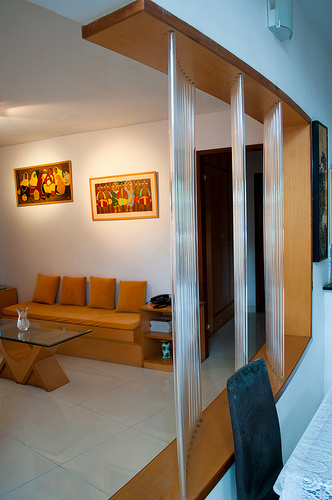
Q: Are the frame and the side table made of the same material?
A: Yes, both the frame and the side table are made of wood.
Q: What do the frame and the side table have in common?
A: The material, both the frame and the side table are wooden.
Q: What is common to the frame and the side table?
A: The material, both the frame and the side table are wooden.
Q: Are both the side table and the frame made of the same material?
A: Yes, both the side table and the frame are made of wood.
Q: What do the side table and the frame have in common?
A: The material, both the side table and the frame are wooden.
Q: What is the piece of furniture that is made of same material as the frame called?
A: The piece of furniture is a side table.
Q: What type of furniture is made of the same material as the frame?
A: The side table is made of the same material as the frame.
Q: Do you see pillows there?
A: Yes, there is a pillow.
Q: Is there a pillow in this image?
A: Yes, there is a pillow.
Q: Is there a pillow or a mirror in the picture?
A: Yes, there is a pillow.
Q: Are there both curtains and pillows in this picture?
A: No, there is a pillow but no curtains.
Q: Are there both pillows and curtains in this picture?
A: No, there is a pillow but no curtains.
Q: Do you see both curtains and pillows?
A: No, there is a pillow but no curtains.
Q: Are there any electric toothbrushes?
A: No, there are no electric toothbrushes.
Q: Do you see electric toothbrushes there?
A: No, there are no electric toothbrushes.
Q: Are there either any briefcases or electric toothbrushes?
A: No, there are no electric toothbrushes or briefcases.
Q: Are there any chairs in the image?
A: Yes, there is a chair.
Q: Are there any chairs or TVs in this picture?
A: Yes, there is a chair.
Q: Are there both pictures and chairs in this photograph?
A: Yes, there are both a chair and a picture.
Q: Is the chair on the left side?
A: No, the chair is on the right of the image.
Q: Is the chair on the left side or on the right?
A: The chair is on the right of the image.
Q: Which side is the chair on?
A: The chair is on the right of the image.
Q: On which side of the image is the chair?
A: The chair is on the right of the image.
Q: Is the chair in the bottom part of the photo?
A: Yes, the chair is in the bottom of the image.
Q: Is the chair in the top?
A: No, the chair is in the bottom of the image.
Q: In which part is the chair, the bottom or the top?
A: The chair is in the bottom of the image.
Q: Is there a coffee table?
A: Yes, there is a coffee table.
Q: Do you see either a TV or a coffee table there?
A: Yes, there is a coffee table.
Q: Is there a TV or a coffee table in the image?
A: Yes, there is a coffee table.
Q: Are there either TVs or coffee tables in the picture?
A: Yes, there is a coffee table.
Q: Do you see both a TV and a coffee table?
A: No, there is a coffee table but no televisions.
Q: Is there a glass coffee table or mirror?
A: Yes, there is a glass coffee table.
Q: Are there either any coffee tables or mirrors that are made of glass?
A: Yes, the coffee table is made of glass.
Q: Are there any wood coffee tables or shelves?
A: Yes, there is a wood coffee table.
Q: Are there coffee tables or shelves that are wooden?
A: Yes, the coffee table is wooden.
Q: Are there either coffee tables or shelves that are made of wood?
A: Yes, the coffee table is made of wood.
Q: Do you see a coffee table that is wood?
A: Yes, there is a wood coffee table.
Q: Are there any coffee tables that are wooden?
A: Yes, there is a coffee table that is wooden.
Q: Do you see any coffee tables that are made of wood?
A: Yes, there is a coffee table that is made of wood.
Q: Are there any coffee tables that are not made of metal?
A: Yes, there is a coffee table that is made of wood.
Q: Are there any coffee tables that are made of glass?
A: Yes, there is a coffee table that is made of glass.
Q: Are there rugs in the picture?
A: No, there are no rugs.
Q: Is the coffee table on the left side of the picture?
A: Yes, the coffee table is on the left of the image.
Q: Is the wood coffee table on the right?
A: No, the coffee table is on the left of the image.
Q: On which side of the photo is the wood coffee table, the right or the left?
A: The coffee table is on the left of the image.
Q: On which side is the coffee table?
A: The coffee table is on the left of the image.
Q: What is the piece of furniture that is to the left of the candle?
A: The piece of furniture is a coffee table.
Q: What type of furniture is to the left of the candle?
A: The piece of furniture is a coffee table.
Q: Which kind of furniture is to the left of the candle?
A: The piece of furniture is a coffee table.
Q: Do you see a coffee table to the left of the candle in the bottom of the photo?
A: Yes, there is a coffee table to the left of the candle.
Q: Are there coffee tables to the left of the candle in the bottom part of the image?
A: Yes, there is a coffee table to the left of the candle.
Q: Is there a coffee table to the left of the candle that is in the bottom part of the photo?
A: Yes, there is a coffee table to the left of the candle.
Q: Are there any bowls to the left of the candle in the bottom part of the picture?
A: No, there is a coffee table to the left of the candle.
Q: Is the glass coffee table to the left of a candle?
A: Yes, the coffee table is to the left of a candle.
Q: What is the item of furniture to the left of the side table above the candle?
A: The piece of furniture is a coffee table.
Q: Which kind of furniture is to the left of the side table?
A: The piece of furniture is a coffee table.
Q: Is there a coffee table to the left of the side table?
A: Yes, there is a coffee table to the left of the side table.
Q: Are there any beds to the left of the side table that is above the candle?
A: No, there is a coffee table to the left of the side table.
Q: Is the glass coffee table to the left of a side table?
A: Yes, the coffee table is to the left of a side table.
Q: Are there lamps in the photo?
A: No, there are no lamps.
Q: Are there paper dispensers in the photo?
A: No, there are no paper dispensers.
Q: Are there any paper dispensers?
A: No, there are no paper dispensers.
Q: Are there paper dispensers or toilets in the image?
A: No, there are no paper dispensers or toilets.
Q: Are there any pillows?
A: Yes, there is a pillow.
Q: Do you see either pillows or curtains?
A: Yes, there is a pillow.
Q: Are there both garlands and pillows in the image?
A: No, there is a pillow but no garlands.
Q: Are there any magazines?
A: No, there are no magazines.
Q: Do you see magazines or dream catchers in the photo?
A: No, there are no magazines or dream catchers.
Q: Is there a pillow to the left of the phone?
A: Yes, there is a pillow to the left of the phone.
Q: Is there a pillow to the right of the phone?
A: No, the pillow is to the left of the phone.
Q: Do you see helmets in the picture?
A: No, there are no helmets.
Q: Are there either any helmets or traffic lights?
A: No, there are no helmets or traffic lights.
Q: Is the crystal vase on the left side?
A: Yes, the vase is on the left of the image.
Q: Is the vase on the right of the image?
A: No, the vase is on the left of the image.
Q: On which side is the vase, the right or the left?
A: The vase is on the left of the image.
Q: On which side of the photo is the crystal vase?
A: The vase is on the left of the image.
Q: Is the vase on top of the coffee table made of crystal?
A: Yes, the vase is made of crystal.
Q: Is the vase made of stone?
A: No, the vase is made of crystal.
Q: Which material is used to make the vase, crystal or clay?
A: The vase is made of crystal.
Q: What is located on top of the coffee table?
A: The vase is on top of the coffee table.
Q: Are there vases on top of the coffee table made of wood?
A: Yes, there is a vase on top of the coffee table.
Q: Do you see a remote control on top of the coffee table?
A: No, there is a vase on top of the coffee table.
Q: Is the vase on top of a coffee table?
A: Yes, the vase is on top of a coffee table.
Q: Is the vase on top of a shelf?
A: No, the vase is on top of a coffee table.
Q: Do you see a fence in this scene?
A: No, there are no fences.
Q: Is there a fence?
A: No, there are no fences.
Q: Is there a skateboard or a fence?
A: No, there are no fences or skateboards.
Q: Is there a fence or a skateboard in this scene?
A: No, there are no fences or skateboards.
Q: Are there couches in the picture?
A: Yes, there is a couch.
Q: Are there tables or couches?
A: Yes, there is a couch.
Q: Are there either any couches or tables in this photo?
A: Yes, there is a couch.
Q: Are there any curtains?
A: No, there are no curtains.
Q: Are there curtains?
A: No, there are no curtains.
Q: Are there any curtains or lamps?
A: No, there are no curtains or lamps.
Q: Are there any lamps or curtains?
A: No, there are no curtains or lamps.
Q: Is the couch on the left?
A: Yes, the couch is on the left of the image.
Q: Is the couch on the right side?
A: No, the couch is on the left of the image.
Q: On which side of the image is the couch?
A: The couch is on the left of the image.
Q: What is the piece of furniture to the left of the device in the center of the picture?
A: The piece of furniture is a couch.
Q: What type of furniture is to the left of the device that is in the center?
A: The piece of furniture is a couch.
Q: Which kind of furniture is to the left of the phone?
A: The piece of furniture is a couch.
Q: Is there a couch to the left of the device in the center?
A: Yes, there is a couch to the left of the phone.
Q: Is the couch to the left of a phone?
A: Yes, the couch is to the left of a phone.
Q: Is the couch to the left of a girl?
A: No, the couch is to the left of a phone.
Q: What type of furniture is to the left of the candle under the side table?
A: The piece of furniture is a couch.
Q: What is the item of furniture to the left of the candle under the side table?
A: The piece of furniture is a couch.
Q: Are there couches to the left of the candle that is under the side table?
A: Yes, there is a couch to the left of the candle.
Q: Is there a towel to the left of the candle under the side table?
A: No, there is a couch to the left of the candle.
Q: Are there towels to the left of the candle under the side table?
A: No, there is a couch to the left of the candle.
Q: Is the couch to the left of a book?
A: No, the couch is to the left of the candle.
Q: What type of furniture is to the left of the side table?
A: The piece of furniture is a couch.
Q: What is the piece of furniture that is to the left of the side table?
A: The piece of furniture is a couch.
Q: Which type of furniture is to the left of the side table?
A: The piece of furniture is a couch.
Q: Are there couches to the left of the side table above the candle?
A: Yes, there is a couch to the left of the side table.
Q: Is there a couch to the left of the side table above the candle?
A: Yes, there is a couch to the left of the side table.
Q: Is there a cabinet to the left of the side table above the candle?
A: No, there is a couch to the left of the side table.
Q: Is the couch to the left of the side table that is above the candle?
A: Yes, the couch is to the left of the side table.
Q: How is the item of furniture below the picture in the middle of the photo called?
A: The piece of furniture is a couch.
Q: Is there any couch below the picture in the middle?
A: Yes, there is a couch below the picture.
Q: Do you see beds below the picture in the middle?
A: No, there is a couch below the picture.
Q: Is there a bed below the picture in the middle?
A: No, there is a couch below the picture.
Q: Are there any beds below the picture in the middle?
A: No, there is a couch below the picture.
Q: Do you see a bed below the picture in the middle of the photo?
A: No, there is a couch below the picture.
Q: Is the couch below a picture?
A: Yes, the couch is below a picture.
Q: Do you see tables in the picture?
A: Yes, there is a table.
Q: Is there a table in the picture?
A: Yes, there is a table.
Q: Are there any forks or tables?
A: Yes, there is a table.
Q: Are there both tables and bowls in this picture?
A: No, there is a table but no bowls.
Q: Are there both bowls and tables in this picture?
A: No, there is a table but no bowls.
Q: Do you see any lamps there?
A: No, there are no lamps.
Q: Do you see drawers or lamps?
A: No, there are no lamps or drawers.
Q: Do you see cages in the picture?
A: No, there are no cages.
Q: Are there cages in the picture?
A: No, there are no cages.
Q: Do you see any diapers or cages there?
A: No, there are no cages or diapers.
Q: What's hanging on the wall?
A: The picture is hanging on the wall.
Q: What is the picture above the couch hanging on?
A: The picture is hanging on the wall.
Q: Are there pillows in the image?
A: Yes, there is a pillow.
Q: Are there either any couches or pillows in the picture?
A: Yes, there is a pillow.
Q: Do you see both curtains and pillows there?
A: No, there is a pillow but no curtains.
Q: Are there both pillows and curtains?
A: No, there is a pillow but no curtains.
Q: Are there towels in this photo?
A: No, there are no towels.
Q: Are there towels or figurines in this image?
A: No, there are no towels or figurines.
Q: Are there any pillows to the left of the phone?
A: Yes, there is a pillow to the left of the phone.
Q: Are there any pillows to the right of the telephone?
A: No, the pillow is to the left of the telephone.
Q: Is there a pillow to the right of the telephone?
A: No, the pillow is to the left of the telephone.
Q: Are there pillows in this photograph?
A: Yes, there is a pillow.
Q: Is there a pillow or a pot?
A: Yes, there is a pillow.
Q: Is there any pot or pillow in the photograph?
A: Yes, there is a pillow.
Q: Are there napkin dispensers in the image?
A: No, there are no napkin dispensers.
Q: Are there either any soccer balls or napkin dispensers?
A: No, there are no napkin dispensers or soccer balls.